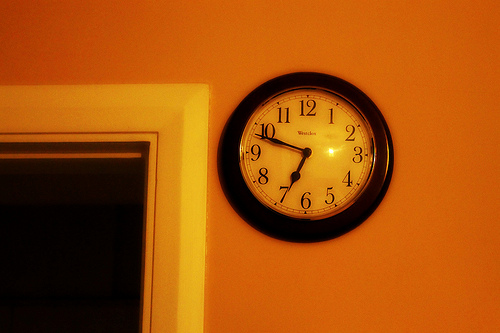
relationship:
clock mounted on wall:
[217, 71, 393, 244] [1, 1, 499, 333]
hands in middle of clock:
[254, 133, 313, 192] [217, 71, 393, 244]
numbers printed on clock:
[249, 96, 364, 210] [217, 71, 393, 244]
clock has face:
[217, 71, 393, 244] [237, 88, 372, 218]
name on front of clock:
[296, 130, 318, 137] [217, 71, 393, 244]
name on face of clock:
[296, 130, 318, 137] [217, 71, 393, 244]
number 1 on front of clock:
[326, 106, 336, 125] [217, 71, 393, 244]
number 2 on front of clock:
[342, 123, 358, 145] [217, 71, 393, 244]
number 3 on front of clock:
[350, 144, 363, 164] [217, 71, 393, 244]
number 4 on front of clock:
[340, 166, 354, 189] [217, 71, 393, 244]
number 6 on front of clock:
[297, 189, 313, 212] [217, 71, 393, 244]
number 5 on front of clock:
[322, 183, 336, 208] [217, 71, 393, 244]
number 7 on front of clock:
[275, 182, 289, 206] [217, 71, 393, 244]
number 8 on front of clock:
[256, 166, 269, 185] [217, 71, 393, 244]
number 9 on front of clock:
[248, 140, 264, 162] [217, 71, 393, 244]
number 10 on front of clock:
[257, 120, 276, 142] [217, 71, 393, 244]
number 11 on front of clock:
[275, 103, 291, 125] [217, 71, 393, 244]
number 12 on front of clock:
[298, 98, 318, 117] [217, 71, 393, 244]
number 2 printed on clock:
[342, 123, 358, 145] [217, 71, 393, 244]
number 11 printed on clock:
[275, 103, 291, 125] [217, 71, 393, 244]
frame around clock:
[237, 88, 372, 218] [217, 71, 393, 244]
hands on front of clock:
[254, 133, 313, 192] [217, 71, 393, 244]